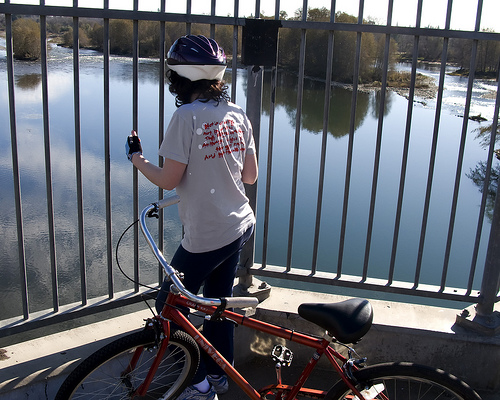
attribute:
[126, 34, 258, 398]
person — female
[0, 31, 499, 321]
water — large, calm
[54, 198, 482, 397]
bicycle — red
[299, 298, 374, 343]
seat — black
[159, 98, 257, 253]
shirt — short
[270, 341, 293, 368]
petal — silver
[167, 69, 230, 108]
hair — curly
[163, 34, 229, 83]
helmet — black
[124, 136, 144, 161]
glove — black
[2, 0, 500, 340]
fence — metal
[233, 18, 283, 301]
pole — thick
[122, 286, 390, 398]
frame — red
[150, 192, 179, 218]
handle — black